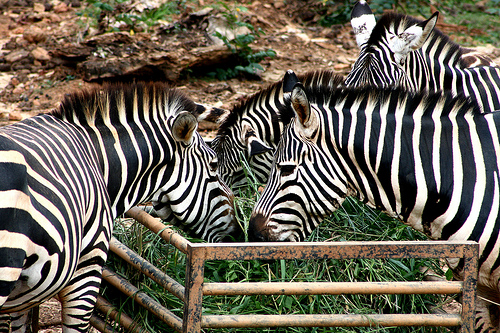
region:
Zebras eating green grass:
[1, 0, 498, 330]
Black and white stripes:
[0, 82, 243, 332]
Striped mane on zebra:
[57, 84, 203, 126]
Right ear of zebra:
[171, 109, 195, 149]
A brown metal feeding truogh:
[97, 207, 476, 331]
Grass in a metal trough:
[104, 177, 444, 332]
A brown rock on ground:
[52, 16, 267, 81]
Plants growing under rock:
[204, 27, 275, 84]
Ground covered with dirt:
[2, 16, 405, 134]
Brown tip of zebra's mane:
[65, 83, 194, 102]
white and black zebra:
[271, 99, 433, 215]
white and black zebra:
[27, 88, 192, 260]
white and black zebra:
[210, 85, 270, 149]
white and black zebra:
[357, 24, 499, 99]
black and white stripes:
[349, 108, 470, 213]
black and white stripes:
[0, 115, 205, 263]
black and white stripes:
[223, 91, 277, 155]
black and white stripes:
[353, 16, 498, 94]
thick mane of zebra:
[335, 74, 470, 116]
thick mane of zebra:
[71, 80, 165, 115]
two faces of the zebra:
[74, 60, 375, 331]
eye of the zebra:
[266, 148, 329, 215]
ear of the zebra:
[283, 70, 347, 178]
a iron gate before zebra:
[219, 219, 441, 330]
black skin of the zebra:
[394, 113, 420, 210]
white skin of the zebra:
[433, 109, 453, 201]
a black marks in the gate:
[459, 240, 480, 330]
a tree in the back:
[36, 17, 316, 104]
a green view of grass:
[173, 226, 356, 301]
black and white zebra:
[246, 95, 498, 287]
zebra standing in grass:
[2, 84, 241, 331]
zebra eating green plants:
[347, 16, 499, 116]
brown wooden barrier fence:
[187, 244, 479, 331]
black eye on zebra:
[279, 163, 296, 175]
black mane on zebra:
[310, 84, 475, 111]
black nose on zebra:
[246, 217, 271, 240]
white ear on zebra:
[171, 110, 197, 139]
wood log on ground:
[59, 11, 242, 76]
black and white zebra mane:
[58, 84, 195, 122]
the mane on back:
[55, 11, 486, 121]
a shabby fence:
[92, 207, 484, 332]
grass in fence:
[92, 146, 462, 331]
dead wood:
[43, 4, 269, 87]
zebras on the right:
[212, 6, 498, 332]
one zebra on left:
[1, 78, 237, 332]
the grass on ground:
[73, 0, 498, 75]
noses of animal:
[219, 213, 276, 240]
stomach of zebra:
[9, 219, 83, 309]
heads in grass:
[164, 11, 441, 240]